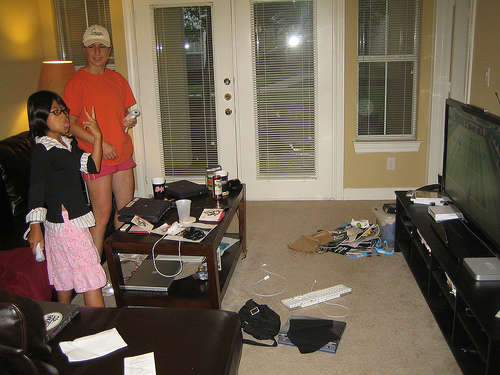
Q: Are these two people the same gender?
A: Yes, all the people are female.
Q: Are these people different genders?
A: No, all the people are female.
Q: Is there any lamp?
A: Yes, there is a lamp.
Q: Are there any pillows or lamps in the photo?
A: Yes, there is a lamp.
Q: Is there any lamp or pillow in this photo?
A: Yes, there is a lamp.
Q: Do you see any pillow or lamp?
A: Yes, there is a lamp.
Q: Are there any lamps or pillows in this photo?
A: Yes, there is a lamp.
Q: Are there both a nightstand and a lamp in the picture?
A: No, there is a lamp but no nightstands.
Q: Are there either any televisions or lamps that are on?
A: Yes, the lamp is on.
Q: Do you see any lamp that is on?
A: Yes, there is a lamp that is on.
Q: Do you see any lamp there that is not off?
A: Yes, there is a lamp that is on .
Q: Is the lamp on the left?
A: Yes, the lamp is on the left of the image.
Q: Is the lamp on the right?
A: No, the lamp is on the left of the image.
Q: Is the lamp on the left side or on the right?
A: The lamp is on the left of the image.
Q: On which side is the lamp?
A: The lamp is on the left of the image.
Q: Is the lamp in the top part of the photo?
A: Yes, the lamp is in the top of the image.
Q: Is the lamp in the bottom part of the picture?
A: No, the lamp is in the top of the image.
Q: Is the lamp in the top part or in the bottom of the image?
A: The lamp is in the top of the image.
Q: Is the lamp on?
A: Yes, the lamp is on.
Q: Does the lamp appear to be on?
A: Yes, the lamp is on.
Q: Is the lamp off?
A: No, the lamp is on.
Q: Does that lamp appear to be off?
A: No, the lamp is on.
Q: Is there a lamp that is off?
A: No, there is a lamp but it is on.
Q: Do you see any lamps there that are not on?
A: No, there is a lamp but it is on.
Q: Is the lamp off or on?
A: The lamp is on.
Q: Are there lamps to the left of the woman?
A: Yes, there is a lamp to the left of the woman.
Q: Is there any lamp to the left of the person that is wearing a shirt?
A: Yes, there is a lamp to the left of the woman.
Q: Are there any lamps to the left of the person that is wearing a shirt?
A: Yes, there is a lamp to the left of the woman.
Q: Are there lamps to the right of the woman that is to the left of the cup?
A: No, the lamp is to the left of the woman.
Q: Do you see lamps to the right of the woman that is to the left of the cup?
A: No, the lamp is to the left of the woman.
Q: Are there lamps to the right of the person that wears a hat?
A: No, the lamp is to the left of the woman.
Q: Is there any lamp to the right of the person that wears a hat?
A: No, the lamp is to the left of the woman.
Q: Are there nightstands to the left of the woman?
A: No, there is a lamp to the left of the woman.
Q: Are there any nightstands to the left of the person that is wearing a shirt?
A: No, there is a lamp to the left of the woman.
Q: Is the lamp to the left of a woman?
A: Yes, the lamp is to the left of a woman.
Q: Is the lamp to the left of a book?
A: No, the lamp is to the left of a woman.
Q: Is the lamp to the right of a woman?
A: No, the lamp is to the left of a woman.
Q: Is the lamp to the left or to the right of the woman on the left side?
A: The lamp is to the left of the woman.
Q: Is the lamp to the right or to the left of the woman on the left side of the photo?
A: The lamp is to the left of the woman.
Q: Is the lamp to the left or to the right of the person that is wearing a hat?
A: The lamp is to the left of the woman.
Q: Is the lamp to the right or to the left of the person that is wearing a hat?
A: The lamp is to the left of the woman.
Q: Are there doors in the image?
A: Yes, there is a door.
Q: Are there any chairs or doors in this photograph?
A: Yes, there is a door.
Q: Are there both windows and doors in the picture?
A: Yes, there are both a door and windows.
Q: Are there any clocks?
A: No, there are no clocks.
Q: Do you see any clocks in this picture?
A: No, there are no clocks.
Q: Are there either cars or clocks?
A: No, there are no clocks or cars.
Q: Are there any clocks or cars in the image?
A: No, there are no clocks or cars.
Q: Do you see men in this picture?
A: No, there are no men.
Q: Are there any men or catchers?
A: No, there are no men or catchers.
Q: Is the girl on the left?
A: Yes, the girl is on the left of the image.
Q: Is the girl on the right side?
A: No, the girl is on the left of the image.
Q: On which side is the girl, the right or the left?
A: The girl is on the left of the image.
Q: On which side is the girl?
A: The girl is on the left of the image.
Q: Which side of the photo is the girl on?
A: The girl is on the left of the image.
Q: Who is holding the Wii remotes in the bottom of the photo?
A: The girl is holding the Wii controller.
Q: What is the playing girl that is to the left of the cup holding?
A: The girl is holding the Wii controller.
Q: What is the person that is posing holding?
A: The girl is holding the Wii controller.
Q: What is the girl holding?
A: The girl is holding the Wii controller.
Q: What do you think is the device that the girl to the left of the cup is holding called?
A: The device is a Wii controller.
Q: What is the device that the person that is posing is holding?
A: The device is a Wii controller.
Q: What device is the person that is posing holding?
A: The girl is holding the Wii controller.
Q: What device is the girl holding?
A: The girl is holding the Wii controller.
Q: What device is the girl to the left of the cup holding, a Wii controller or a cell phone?
A: The girl is holding a Wii controller.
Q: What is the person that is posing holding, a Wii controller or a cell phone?
A: The girl is holding a Wii controller.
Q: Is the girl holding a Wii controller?
A: Yes, the girl is holding a Wii controller.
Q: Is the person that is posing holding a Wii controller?
A: Yes, the girl is holding a Wii controller.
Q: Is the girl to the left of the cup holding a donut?
A: No, the girl is holding a Wii controller.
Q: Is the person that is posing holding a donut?
A: No, the girl is holding a Wii controller.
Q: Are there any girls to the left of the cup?
A: Yes, there is a girl to the left of the cup.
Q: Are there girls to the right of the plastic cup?
A: No, the girl is to the left of the cup.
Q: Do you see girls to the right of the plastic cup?
A: No, the girl is to the left of the cup.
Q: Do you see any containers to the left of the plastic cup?
A: No, there is a girl to the left of the cup.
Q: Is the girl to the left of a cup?
A: Yes, the girl is to the left of a cup.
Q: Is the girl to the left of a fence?
A: No, the girl is to the left of a cup.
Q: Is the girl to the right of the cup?
A: No, the girl is to the left of the cup.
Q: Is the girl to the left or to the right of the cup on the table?
A: The girl is to the left of the cup.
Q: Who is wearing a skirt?
A: The girl is wearing a skirt.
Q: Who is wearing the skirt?
A: The girl is wearing a skirt.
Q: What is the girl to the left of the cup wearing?
A: The girl is wearing a skirt.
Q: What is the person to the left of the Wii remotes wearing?
A: The girl is wearing a skirt.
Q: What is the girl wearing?
A: The girl is wearing a skirt.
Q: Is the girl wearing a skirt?
A: Yes, the girl is wearing a skirt.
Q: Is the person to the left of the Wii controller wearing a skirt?
A: Yes, the girl is wearing a skirt.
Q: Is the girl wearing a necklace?
A: No, the girl is wearing a skirt.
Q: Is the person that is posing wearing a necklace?
A: No, the girl is wearing a skirt.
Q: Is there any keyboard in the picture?
A: Yes, there is a keyboard.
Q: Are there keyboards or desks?
A: Yes, there is a keyboard.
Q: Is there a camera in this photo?
A: No, there are no cameras.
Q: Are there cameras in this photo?
A: No, there are no cameras.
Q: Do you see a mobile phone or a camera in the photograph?
A: No, there are no cameras or cell phones.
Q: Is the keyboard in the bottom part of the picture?
A: Yes, the keyboard is in the bottom of the image.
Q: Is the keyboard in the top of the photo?
A: No, the keyboard is in the bottom of the image.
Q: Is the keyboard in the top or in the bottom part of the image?
A: The keyboard is in the bottom of the image.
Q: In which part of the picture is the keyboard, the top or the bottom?
A: The keyboard is in the bottom of the image.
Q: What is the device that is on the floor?
A: The device is a keyboard.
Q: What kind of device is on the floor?
A: The device is a keyboard.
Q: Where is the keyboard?
A: The keyboard is on the floor.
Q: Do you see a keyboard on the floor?
A: Yes, there is a keyboard on the floor.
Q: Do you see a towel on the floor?
A: No, there is a keyboard on the floor.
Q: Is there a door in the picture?
A: Yes, there is a door.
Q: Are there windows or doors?
A: Yes, there is a door.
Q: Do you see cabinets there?
A: No, there are no cabinets.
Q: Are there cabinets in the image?
A: No, there are no cabinets.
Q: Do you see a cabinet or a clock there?
A: No, there are no cabinets or clocks.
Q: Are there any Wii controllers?
A: Yes, there is a Wii controller.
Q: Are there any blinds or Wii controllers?
A: Yes, there is a Wii controller.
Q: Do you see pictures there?
A: No, there are no pictures.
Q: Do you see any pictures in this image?
A: No, there are no pictures.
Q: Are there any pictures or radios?
A: No, there are no pictures or radios.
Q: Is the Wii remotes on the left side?
A: Yes, the Wii remotes is on the left of the image.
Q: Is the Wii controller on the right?
A: No, the Wii controller is on the left of the image.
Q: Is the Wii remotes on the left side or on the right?
A: The Wii remotes is on the left of the image.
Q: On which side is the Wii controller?
A: The Wii controller is on the left of the image.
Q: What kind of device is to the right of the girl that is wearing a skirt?
A: The device is a Wii controller.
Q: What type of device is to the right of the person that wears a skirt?
A: The device is a Wii controller.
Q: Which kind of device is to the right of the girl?
A: The device is a Wii controller.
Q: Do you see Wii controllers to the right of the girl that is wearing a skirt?
A: Yes, there is a Wii controller to the right of the girl.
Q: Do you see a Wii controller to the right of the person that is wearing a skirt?
A: Yes, there is a Wii controller to the right of the girl.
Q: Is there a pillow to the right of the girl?
A: No, there is a Wii controller to the right of the girl.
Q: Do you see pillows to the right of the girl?
A: No, there is a Wii controller to the right of the girl.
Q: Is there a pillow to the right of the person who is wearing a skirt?
A: No, there is a Wii controller to the right of the girl.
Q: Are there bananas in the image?
A: No, there are no bananas.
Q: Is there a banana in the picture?
A: No, there are no bananas.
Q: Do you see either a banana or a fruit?
A: No, there are no bananas or fruits.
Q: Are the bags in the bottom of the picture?
A: Yes, the bags are in the bottom of the image.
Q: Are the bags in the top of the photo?
A: No, the bags are in the bottom of the image.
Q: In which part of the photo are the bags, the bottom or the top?
A: The bags are in the bottom of the image.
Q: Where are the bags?
A: The bags are on the floor.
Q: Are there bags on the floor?
A: Yes, there are bags on the floor.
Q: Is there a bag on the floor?
A: Yes, there are bags on the floor.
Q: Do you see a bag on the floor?
A: Yes, there are bags on the floor.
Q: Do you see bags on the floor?
A: Yes, there are bags on the floor.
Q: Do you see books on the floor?
A: No, there are bags on the floor.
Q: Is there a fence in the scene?
A: No, there are no fences.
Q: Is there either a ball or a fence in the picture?
A: No, there are no fences or balls.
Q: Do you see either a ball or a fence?
A: No, there are no fences or balls.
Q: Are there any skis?
A: No, there are no skis.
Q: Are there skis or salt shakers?
A: No, there are no skis or salt shakers.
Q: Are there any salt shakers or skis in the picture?
A: No, there are no skis or salt shakers.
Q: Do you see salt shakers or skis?
A: No, there are no skis or salt shakers.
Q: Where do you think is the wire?
A: The wire is on the floor.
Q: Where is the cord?
A: The wire is on the floor.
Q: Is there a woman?
A: Yes, there is a woman.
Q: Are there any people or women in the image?
A: Yes, there is a woman.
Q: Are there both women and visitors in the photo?
A: No, there is a woman but no visitors.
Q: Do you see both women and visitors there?
A: No, there is a woman but no visitors.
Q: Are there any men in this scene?
A: No, there are no men.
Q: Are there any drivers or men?
A: No, there are no men or drivers.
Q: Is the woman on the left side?
A: Yes, the woman is on the left of the image.